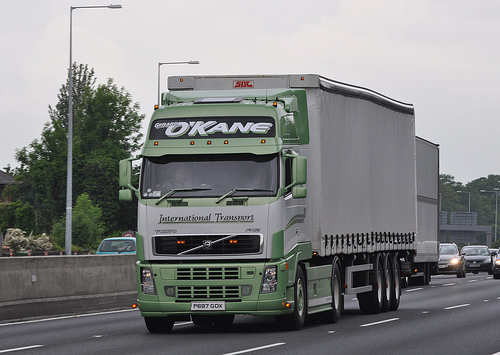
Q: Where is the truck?
A: On road.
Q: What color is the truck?
A: Green and white.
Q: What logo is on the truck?
A: O'Kane.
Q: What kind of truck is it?
A: Transport.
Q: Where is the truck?
A: On highway.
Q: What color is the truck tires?
A: Black.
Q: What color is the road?
A: Gray.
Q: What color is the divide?
A: Gray.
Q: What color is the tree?
A: Green.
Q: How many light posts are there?
A: 2.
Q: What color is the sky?
A: Overcast and gray.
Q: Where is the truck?
A: On a street.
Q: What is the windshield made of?
A: Glass.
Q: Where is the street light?
A: On the street.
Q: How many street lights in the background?
A: Two.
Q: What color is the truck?
A: Gray and green.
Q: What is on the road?
A: A truck.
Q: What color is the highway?
A: Gray.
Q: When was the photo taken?
A: Daytime.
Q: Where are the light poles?
A: Along the roadway.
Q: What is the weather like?
A: Overcast.